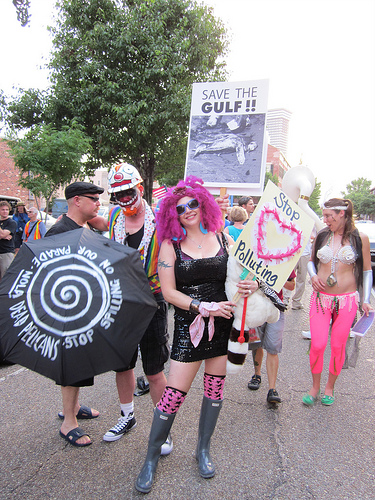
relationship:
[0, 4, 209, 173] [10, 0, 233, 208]
leaves are from tree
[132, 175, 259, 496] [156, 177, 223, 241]
lady has hair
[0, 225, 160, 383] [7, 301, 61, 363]
umbrella objecting to dead pelicans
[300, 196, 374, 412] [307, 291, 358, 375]
lady wearing pants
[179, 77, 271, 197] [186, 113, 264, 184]
sign with photo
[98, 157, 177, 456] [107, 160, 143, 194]
man wearing hat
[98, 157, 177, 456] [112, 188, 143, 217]
man wearing face paint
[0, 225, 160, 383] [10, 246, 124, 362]
umbrella has writing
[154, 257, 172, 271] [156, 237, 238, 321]
tattoo on arm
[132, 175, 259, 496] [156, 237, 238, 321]
lady has arm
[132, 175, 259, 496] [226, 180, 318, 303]
lady holding poster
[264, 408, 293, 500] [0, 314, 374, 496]
crack in pavment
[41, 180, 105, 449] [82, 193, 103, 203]
man wearing glasses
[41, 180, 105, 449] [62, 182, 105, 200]
man wearing cap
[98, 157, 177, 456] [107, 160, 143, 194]
man in hat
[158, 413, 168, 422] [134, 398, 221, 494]
label on boots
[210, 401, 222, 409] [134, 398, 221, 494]
label on boots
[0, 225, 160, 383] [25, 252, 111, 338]
umbrella has design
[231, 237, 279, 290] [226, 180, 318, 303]
writing on poster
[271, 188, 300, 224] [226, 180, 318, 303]
writing on poster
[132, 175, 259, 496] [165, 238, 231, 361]
lady wearing dress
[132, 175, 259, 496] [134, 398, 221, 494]
lady wearing boots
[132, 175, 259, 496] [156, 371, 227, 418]
lady wearing socks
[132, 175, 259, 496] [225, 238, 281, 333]
lady carrying stuffed animal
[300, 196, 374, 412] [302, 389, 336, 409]
lady wearing shoes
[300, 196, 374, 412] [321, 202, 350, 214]
lady wearing head band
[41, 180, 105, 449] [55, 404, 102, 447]
man wearing sandals